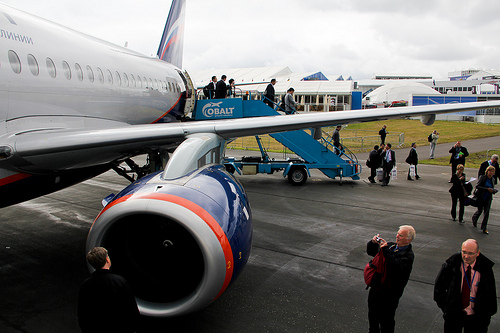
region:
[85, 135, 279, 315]
air plane wing engine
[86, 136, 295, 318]
silver and blue engine with red stripe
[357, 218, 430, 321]
older man holding a camera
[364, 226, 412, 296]
man holding a red bag pack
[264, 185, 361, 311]
gray airport runway floor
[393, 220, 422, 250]
man with white hair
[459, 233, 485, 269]
man with bald head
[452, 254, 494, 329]
man with pink dress shirt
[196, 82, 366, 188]
blue steal air port stairs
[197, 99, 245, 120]
Obalt logo on steal wall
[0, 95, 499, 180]
wing of an airplane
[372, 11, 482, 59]
a white cloud in sky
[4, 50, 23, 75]
small window of airplane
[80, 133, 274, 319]
large engine of airplane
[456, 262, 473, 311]
red tie around man's neck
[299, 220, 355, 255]
dark colored pavement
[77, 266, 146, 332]
a black jacket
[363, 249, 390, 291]
a red and black bag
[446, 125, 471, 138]
green and yellow grass on ground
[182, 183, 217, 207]
red and blue paint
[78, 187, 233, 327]
man peering into the engine of a plane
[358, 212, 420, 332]
man holding a camera and a red backpack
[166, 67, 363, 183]
people exiting the plane down a blue staircase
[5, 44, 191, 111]
round windows on a plane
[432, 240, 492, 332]
man with a pink shirt and a red tie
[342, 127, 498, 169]
paved walkway through grass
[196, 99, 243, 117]
airlines logo on a blue staircase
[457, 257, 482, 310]
man with a blue lanyard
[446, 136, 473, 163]
man holding a neon green folder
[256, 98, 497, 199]
green grass alongside the tarmac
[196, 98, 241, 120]
'cobalt' logo w/ airplane taking off from the 'c'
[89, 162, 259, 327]
orange red stripe close to front of royal navy blue engine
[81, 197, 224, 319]
silvertone stripe @ end of engine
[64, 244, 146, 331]
man w/ short hair stares, inexplicably, into engine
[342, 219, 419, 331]
older man photographs younger man staring into airplane engine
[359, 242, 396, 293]
older man carries red backppack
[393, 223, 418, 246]
older man has white hair, not an incredible amount of it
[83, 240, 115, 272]
man who stares at engine has brown hair, short, almost wedge-cut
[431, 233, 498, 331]
man, front right corner, has scarcely any hair at all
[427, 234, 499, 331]
man in lower right corner wears pink shirt, dark wide tie, dark jacket, eyeglasses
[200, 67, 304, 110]
People coming off the plane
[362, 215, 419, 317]
A man with a camera taking a picture of the plane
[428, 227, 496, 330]
A man walking by the plane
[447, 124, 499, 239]
a group of people walking to away from the plane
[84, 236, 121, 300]
The back of a man's head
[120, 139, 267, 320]
The gray, blue and orange engine of the plane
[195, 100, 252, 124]
Teh name of the airline in white with blue backdrop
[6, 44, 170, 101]
The windows on the plane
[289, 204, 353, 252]
An asphalt flooring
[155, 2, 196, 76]
The red, white and blue tail of the plane